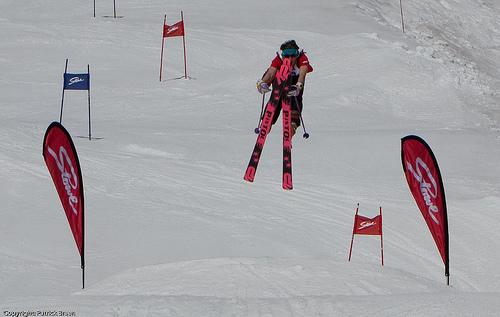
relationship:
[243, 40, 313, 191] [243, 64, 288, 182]
person with ski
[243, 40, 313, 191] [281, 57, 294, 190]
person with ski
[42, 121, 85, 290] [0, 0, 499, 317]
flag in snow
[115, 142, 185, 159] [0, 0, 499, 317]
pile of snow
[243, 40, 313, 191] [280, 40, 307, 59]
person with hair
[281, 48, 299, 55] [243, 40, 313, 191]
headband on person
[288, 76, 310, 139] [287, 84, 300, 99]
ski pole in hand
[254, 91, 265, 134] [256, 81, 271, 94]
ski pole in hand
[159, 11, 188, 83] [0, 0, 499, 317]
flag marking snow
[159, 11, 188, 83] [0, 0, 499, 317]
flag in snow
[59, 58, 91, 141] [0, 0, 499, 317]
track advertisement in snow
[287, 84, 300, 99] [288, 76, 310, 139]
hand grasping ski pole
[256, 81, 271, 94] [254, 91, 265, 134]
hand grasping ski pole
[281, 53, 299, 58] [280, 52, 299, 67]
sunglasses on face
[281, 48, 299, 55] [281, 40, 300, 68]
headband on head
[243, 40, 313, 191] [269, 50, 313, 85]
person wearing shirt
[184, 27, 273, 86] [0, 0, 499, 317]
track in snow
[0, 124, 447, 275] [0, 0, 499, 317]
track in snow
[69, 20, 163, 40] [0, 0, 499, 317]
track in snow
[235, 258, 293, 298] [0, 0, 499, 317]
track in snow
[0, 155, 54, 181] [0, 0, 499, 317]
track in snow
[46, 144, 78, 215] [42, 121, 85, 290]
writing on flag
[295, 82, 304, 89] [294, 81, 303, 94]
wrist band on wrist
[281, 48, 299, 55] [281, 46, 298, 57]
headband around forehead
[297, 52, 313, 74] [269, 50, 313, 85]
sleeve on shirt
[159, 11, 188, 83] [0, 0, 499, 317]
flag against snow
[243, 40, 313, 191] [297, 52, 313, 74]
person wearing sleeve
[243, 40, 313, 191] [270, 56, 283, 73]
person wearing sleeve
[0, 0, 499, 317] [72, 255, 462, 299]
snow in pile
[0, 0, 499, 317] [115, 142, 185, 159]
snow in pile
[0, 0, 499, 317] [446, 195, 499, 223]
snow in pile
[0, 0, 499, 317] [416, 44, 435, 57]
snow in cluster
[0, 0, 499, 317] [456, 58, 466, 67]
snow in cluster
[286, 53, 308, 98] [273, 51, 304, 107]
arm in front of body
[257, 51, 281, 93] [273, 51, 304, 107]
arm in front of body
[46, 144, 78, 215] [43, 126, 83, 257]
writing on fabric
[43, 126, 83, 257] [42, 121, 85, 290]
fabric on flag